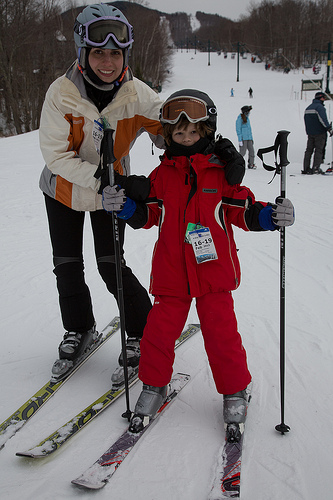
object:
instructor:
[40, 6, 165, 367]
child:
[99, 88, 296, 422]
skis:
[0, 316, 202, 462]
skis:
[73, 373, 255, 499]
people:
[39, 4, 294, 424]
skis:
[0, 317, 249, 499]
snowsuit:
[133, 153, 254, 394]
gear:
[74, 3, 217, 144]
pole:
[257, 131, 293, 435]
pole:
[102, 127, 136, 420]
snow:
[0, 127, 66, 425]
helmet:
[75, 3, 133, 93]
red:
[127, 151, 258, 395]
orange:
[65, 114, 83, 158]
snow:
[1, 311, 333, 499]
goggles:
[83, 18, 135, 48]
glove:
[272, 197, 295, 229]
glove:
[102, 186, 127, 213]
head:
[77, 4, 134, 82]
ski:
[220, 420, 243, 497]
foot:
[223, 385, 246, 425]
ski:
[74, 371, 193, 492]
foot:
[134, 386, 170, 418]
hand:
[272, 195, 297, 229]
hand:
[98, 183, 130, 213]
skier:
[246, 84, 254, 100]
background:
[0, 0, 328, 150]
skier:
[228, 87, 235, 99]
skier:
[190, 54, 196, 59]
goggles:
[159, 95, 212, 124]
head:
[161, 87, 215, 153]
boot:
[223, 390, 247, 425]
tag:
[191, 226, 218, 264]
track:
[242, 437, 332, 499]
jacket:
[39, 74, 167, 212]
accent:
[57, 175, 74, 209]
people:
[226, 85, 256, 101]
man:
[302, 91, 331, 177]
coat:
[304, 99, 332, 137]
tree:
[1, 0, 17, 135]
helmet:
[159, 88, 216, 156]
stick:
[272, 127, 292, 435]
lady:
[237, 105, 258, 171]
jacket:
[236, 112, 252, 141]